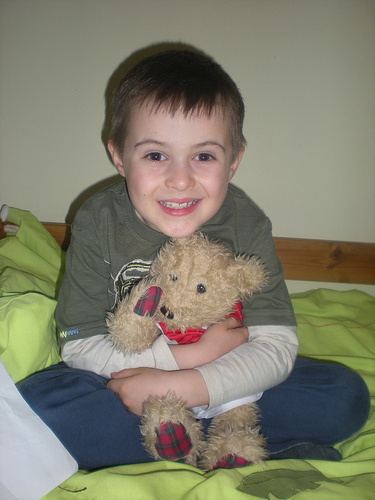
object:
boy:
[13, 42, 370, 469]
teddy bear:
[108, 235, 268, 472]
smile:
[154, 197, 201, 218]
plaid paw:
[134, 287, 162, 317]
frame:
[39, 221, 372, 286]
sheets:
[3, 204, 372, 498]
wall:
[3, 2, 374, 297]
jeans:
[13, 354, 370, 472]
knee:
[333, 359, 371, 442]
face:
[157, 256, 231, 324]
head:
[108, 44, 242, 242]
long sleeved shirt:
[55, 181, 299, 419]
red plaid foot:
[151, 421, 192, 462]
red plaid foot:
[213, 453, 253, 471]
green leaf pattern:
[236, 468, 323, 500]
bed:
[1, 215, 372, 497]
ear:
[232, 255, 267, 296]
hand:
[107, 365, 191, 414]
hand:
[195, 315, 248, 367]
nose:
[165, 164, 197, 191]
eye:
[141, 150, 168, 162]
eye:
[190, 152, 215, 162]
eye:
[196, 283, 204, 291]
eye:
[170, 276, 178, 283]